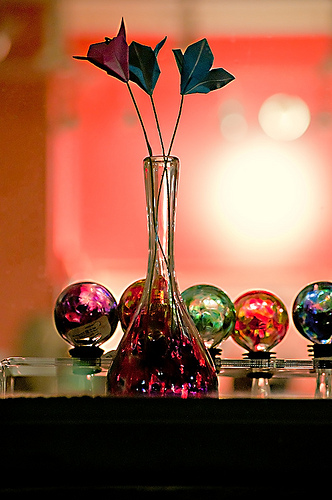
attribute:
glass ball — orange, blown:
[117, 268, 187, 352]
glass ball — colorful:
[59, 285, 137, 334]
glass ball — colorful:
[227, 281, 290, 360]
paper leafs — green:
[129, 37, 167, 99]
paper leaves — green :
[169, 36, 234, 97]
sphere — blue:
[292, 276, 330, 343]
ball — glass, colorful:
[50, 279, 119, 348]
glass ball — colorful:
[50, 279, 119, 349]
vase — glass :
[107, 149, 213, 391]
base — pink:
[97, 324, 229, 388]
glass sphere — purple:
[45, 266, 117, 360]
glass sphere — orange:
[228, 281, 293, 365]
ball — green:
[173, 268, 257, 353]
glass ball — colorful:
[294, 275, 328, 345]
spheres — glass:
[35, 268, 327, 362]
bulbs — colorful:
[46, 262, 331, 375]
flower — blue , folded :
[165, 34, 242, 162]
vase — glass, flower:
[104, 153, 218, 397]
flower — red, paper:
[93, 23, 130, 81]